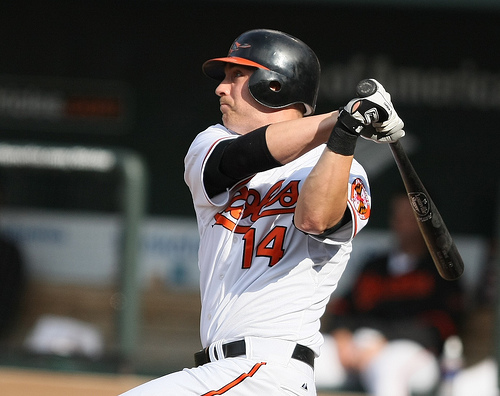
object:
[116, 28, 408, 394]
batter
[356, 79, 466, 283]
bat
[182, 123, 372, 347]
top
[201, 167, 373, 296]
shadow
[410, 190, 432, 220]
sticker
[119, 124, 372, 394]
uniform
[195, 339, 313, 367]
belt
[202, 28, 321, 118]
helmet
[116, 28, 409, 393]
player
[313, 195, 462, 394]
man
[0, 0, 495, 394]
dugout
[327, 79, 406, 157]
gloves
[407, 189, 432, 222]
writing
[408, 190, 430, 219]
logo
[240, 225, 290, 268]
number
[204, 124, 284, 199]
brace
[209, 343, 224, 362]
loop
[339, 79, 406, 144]
hands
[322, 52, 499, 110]
name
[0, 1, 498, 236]
stadium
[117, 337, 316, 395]
pants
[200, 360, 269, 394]
stipe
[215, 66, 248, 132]
face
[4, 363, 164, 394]
field